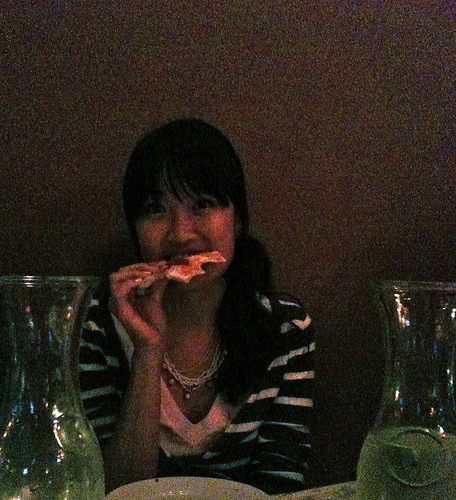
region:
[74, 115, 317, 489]
Woman eating a slice of pizza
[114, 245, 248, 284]
A slice of pizza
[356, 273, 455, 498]
A water vase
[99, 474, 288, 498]
A white plate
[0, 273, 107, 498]
A empty glass vase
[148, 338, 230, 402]
A white and purple necklace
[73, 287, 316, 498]
A black and white striped shirt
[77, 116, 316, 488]
An asian girl with black hair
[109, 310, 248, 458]
A white undershirt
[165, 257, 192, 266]
Pepperoni on a slice of pizza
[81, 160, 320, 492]
Women wearing a striped shirt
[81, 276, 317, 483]
The shirt is black and white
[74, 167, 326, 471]
The women is sitting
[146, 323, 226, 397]
The necklace is silver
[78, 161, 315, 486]
The women is eating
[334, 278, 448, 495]
The bottle is glass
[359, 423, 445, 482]
Slice of lime in the drink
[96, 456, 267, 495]
The plate is white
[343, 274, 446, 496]
The bottle is tall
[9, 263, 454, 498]
Two glass bottles on the table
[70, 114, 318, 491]
woman eating a piece of pizza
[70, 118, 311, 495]
woman wearing a striped shirt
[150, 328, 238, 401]
necklace with round beads on it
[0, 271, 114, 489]
large glass vase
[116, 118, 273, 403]
black hair in a pony tail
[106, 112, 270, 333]
woman who is smiling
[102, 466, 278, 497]
white plate on the table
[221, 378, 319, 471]
black and white stripes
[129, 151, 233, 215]
short black bangs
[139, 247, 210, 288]
pizza with bites taken from it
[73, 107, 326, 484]
woman eating pizza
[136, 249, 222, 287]
slice of pizza being eaten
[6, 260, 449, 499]
glass beverage pitches on table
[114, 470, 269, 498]
white plate on table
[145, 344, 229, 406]
necklace of woman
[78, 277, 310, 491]
black and white striped shirt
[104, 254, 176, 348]
hand holding pizza slice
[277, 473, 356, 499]
edge of table plate is on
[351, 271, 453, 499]
glass pitcher with water in it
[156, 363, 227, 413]
baubles hanging off necklace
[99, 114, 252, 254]
girl with black hair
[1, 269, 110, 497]
clear glass pitcher on table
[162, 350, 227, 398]
necklaces on woman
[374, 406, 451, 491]
piece of lime in glass pitcher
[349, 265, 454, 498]
filled glass pitcher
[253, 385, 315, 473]
black and white stripes on shirt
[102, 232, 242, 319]
piece of pizza in hand of woman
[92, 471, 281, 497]
white dining plate on table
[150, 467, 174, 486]
black speck on side of plate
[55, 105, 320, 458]
woman eating piece of pizza